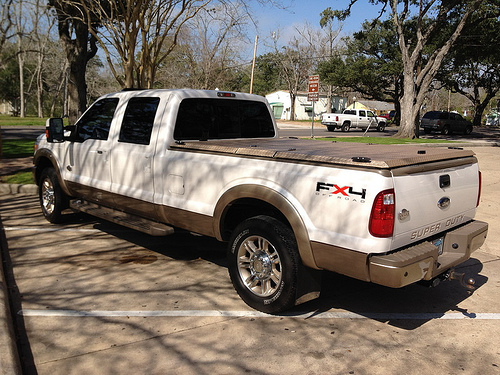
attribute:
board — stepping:
[67, 190, 202, 263]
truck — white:
[317, 106, 394, 135]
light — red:
[367, 182, 413, 252]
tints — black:
[131, 105, 153, 135]